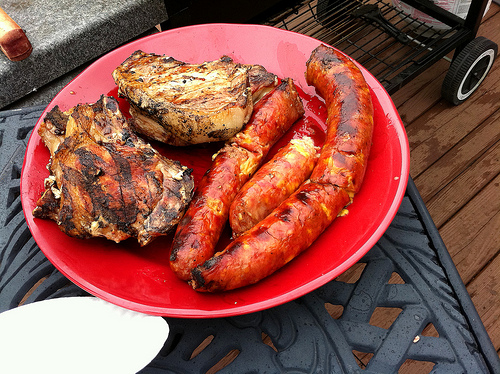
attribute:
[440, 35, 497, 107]
wheel — black 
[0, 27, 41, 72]
tool — wooden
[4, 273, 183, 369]
plate — white 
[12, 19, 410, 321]
plate — round, red, white , paper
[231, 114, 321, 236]
sausage — grilled, cut 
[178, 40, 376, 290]
sausage — red 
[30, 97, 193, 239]
chicken — delicious 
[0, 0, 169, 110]
counter top — granite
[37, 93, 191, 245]
meat type — grilled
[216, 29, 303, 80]
plate — red 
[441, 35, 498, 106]
grill tire — black, white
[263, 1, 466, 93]
basket — Black 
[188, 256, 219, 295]
mark — burn 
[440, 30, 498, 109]
wheel — white , Black 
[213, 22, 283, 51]
plate — red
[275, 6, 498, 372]
floor — wooden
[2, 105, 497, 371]
table — black, metal, outdoor, large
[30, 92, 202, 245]
meat — cooked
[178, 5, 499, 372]
floor — wooden 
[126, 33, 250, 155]
chicken — delicious 